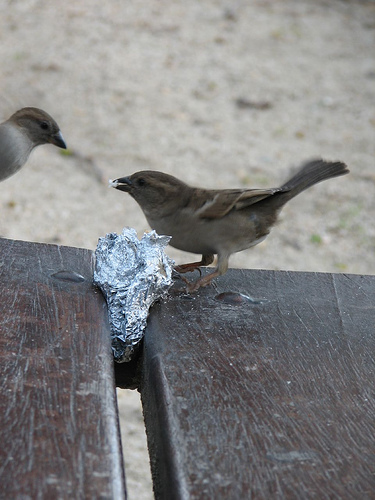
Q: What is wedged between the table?
A: Aluminum foil.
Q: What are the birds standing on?
A: A table.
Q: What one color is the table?
A: Brown.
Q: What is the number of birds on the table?
A: Two.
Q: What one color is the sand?
A: Brown.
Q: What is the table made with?
A: Wood.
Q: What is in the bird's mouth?
A: Tin foil.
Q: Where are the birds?
A: On Table.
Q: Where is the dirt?
A: On the ground.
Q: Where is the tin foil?
A: Between table slats.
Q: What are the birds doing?
A: Standing.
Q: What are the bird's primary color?
A: Brown.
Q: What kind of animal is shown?
A: Birds.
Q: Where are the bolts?
A: In table.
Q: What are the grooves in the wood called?
A: Grain.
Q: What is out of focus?
A: Ground.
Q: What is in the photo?
A: A bird.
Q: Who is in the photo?
A: No one.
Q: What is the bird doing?
A: Feeding.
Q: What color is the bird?
A: Black.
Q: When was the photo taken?
A: Daytime.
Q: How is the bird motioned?
A: Standing.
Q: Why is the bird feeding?
A: Hunger.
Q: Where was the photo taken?
A: At the park.